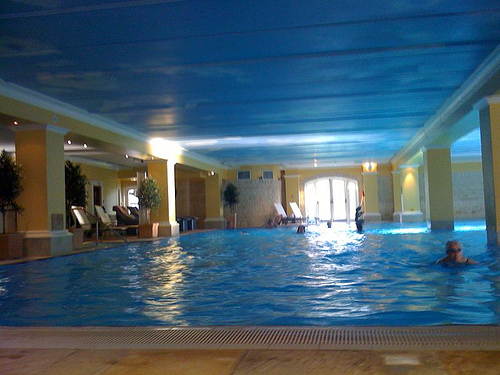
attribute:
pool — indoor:
[2, 207, 497, 325]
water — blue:
[7, 226, 499, 324]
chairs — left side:
[66, 197, 148, 247]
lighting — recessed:
[12, 120, 17, 125]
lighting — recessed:
[82, 142, 87, 147]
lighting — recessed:
[123, 152, 131, 160]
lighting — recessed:
[66, 138, 72, 143]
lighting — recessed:
[208, 170, 214, 175]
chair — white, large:
[70, 195, 141, 238]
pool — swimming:
[163, 210, 377, 310]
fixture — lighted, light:
[403, 170, 411, 181]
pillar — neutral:
[478, 103, 499, 245]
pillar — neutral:
[423, 142, 453, 229]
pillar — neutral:
[363, 166, 379, 221]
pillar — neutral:
[285, 171, 297, 214]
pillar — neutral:
[398, 158, 423, 221]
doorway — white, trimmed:
[84, 179, 121, 244]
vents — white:
[236, 163, 279, 190]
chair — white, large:
[287, 206, 318, 224]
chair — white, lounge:
[69, 191, 124, 276]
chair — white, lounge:
[260, 191, 302, 248]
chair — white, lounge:
[290, 196, 314, 230]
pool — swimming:
[98, 226, 418, 331]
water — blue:
[228, 228, 379, 328]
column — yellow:
[145, 159, 178, 232]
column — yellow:
[18, 122, 71, 248]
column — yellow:
[201, 169, 225, 224]